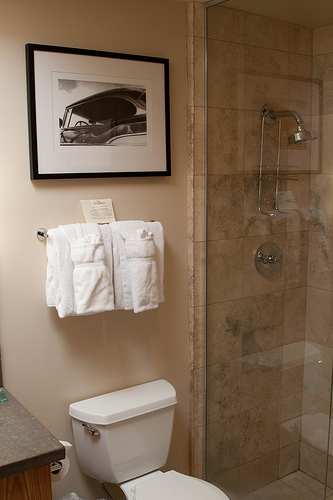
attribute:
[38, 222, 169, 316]
towels — white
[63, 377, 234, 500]
toilet — white, porcelain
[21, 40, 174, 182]
picture — framed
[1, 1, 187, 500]
wall — beige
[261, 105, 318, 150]
showerhead — metal, silver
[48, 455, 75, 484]
toilet paper — white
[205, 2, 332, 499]
door — glass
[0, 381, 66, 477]
counter — black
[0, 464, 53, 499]
cabinet — brown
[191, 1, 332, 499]
shower — tiled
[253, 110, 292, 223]
caddy — metal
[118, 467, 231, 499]
toilet seat cover — closed, white, down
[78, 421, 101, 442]
flush handle — silver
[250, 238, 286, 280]
shower tap — metal